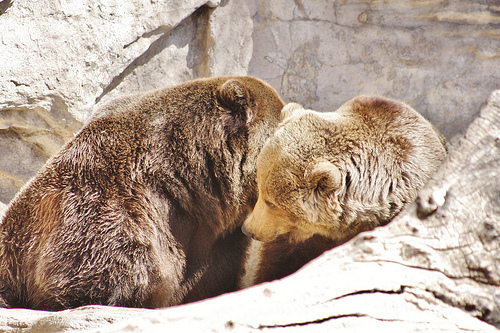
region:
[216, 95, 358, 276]
face of the animal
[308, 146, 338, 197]
ear of the animal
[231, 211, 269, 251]
nose of the animal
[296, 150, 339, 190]
ear of the aniamls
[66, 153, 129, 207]
skin of the animal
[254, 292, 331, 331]
a mark in the tree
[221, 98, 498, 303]
a animal near the tree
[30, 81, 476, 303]
two animals sitting in field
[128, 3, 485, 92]
a hard rock in the back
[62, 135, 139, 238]
fur of the animal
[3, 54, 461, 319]
two brown bears near a trunk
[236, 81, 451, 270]
baby bear has open mouth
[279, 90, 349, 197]
round ears of bear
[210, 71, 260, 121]
round ear of bear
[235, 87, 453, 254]
bear is color brown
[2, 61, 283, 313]
adult bear is color brown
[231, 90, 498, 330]
a trunk in front a bear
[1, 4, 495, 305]
rocks behind two bears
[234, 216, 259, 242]
black nose of bear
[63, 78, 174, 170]
bear has a hump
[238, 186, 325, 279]
brown bear with open mouth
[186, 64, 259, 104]
right ear on dark brown bear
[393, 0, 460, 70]
right side of a rocky wall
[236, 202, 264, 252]
dark black nose on light brown bear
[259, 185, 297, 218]
left eye on light brow bear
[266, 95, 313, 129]
right ear on light brown bear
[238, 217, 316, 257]
snout located on bear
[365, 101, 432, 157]
ruffled fur on bear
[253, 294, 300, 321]
sun reflecting off of a rock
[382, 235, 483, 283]
cracked area on rock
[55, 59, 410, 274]
a pair of brown bears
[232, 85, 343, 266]
the head of a brown bear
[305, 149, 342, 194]
the ear of a brown bear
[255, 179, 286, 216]
the eye of a brown bear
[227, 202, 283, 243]
the snout of a brown bear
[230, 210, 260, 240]
the nose of a brown bear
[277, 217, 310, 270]
the mouth of a brown bear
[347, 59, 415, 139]
the back of a brown bear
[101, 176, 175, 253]
the brown fur of a brown bear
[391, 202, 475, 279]
the edge of a rock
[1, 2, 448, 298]
the rock wall is behind the bears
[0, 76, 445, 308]
the bears are brown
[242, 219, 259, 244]
the nose is black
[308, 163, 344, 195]
the ear is brown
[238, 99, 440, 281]
the bear has ears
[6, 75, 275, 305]
the bear is lying down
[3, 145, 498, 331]
the branch is brown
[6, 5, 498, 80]
the stone wall is grey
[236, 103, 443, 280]
the bear is sitting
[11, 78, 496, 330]
the bears are behind the branch